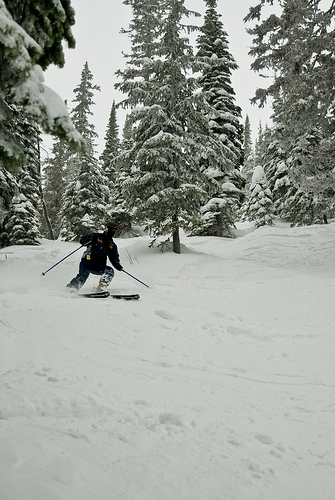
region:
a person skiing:
[40, 220, 150, 298]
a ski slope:
[0, 241, 333, 493]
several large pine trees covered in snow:
[0, 1, 332, 230]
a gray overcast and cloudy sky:
[44, 2, 273, 153]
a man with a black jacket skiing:
[41, 221, 151, 299]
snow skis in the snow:
[72, 291, 138, 299]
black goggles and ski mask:
[108, 226, 115, 237]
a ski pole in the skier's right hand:
[42, 241, 91, 272]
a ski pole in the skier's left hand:
[120, 267, 150, 288]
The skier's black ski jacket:
[77, 234, 120, 266]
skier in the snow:
[48, 214, 158, 303]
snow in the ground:
[21, 361, 277, 457]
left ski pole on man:
[122, 266, 156, 289]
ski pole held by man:
[28, 232, 97, 276]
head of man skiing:
[102, 215, 122, 235]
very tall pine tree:
[118, 24, 213, 253]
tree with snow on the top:
[251, 160, 270, 204]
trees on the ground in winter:
[109, 26, 331, 214]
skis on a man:
[73, 286, 142, 303]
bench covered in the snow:
[0, 246, 19, 263]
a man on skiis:
[50, 218, 157, 309]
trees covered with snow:
[2, 59, 324, 215]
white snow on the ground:
[16, 325, 282, 479]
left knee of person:
[104, 266, 121, 276]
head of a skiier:
[104, 217, 120, 235]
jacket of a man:
[80, 232, 127, 267]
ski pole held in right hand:
[43, 237, 89, 273]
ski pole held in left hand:
[114, 264, 157, 286]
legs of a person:
[64, 260, 116, 300]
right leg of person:
[70, 259, 89, 291]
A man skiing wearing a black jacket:
[38, 207, 160, 312]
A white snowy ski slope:
[50, 332, 327, 483]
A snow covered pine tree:
[108, 1, 237, 264]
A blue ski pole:
[39, 237, 87, 278]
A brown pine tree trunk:
[170, 234, 183, 254]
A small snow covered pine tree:
[242, 161, 279, 230]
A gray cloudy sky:
[81, 6, 112, 56]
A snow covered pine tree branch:
[236, 1, 276, 22]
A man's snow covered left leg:
[92, 265, 116, 292]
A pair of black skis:
[75, 289, 145, 302]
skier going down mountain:
[38, 211, 154, 303]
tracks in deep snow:
[17, 301, 313, 479]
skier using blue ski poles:
[39, 216, 155, 308]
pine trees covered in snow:
[103, 3, 333, 239]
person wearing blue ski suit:
[37, 208, 157, 307]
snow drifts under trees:
[16, 216, 331, 293]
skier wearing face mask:
[33, 213, 147, 309]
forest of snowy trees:
[3, 3, 332, 235]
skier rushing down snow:
[39, 216, 154, 306]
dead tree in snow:
[26, 106, 67, 244]